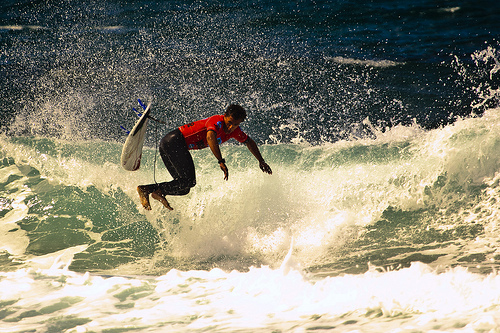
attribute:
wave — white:
[0, 107, 498, 263]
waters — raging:
[0, 1, 497, 331]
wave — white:
[8, 126, 498, 261]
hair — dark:
[222, 103, 248, 122]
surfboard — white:
[115, 94, 163, 175]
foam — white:
[253, 99, 453, 275]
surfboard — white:
[115, 96, 157, 175]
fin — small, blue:
[123, 93, 165, 132]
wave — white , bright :
[164, 187, 375, 304]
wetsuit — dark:
[143, 129, 202, 199]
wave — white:
[15, 116, 464, 278]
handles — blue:
[131, 95, 142, 124]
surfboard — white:
[122, 93, 156, 173]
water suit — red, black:
[138, 113, 248, 197]